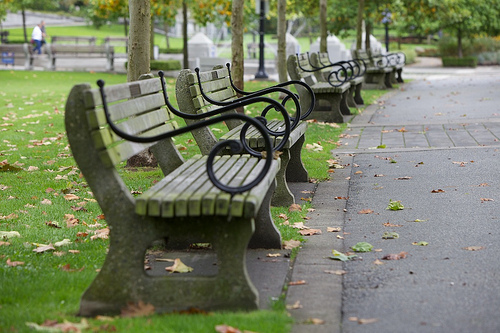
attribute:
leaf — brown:
[31, 238, 53, 249]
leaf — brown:
[376, 242, 413, 268]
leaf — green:
[382, 193, 410, 217]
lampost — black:
[380, 10, 392, 51]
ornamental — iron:
[99, 97, 267, 189]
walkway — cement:
[342, 68, 496, 328]